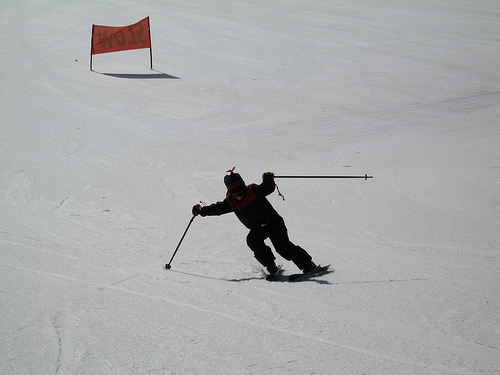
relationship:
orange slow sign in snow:
[90, 14, 155, 76] [4, 4, 496, 372]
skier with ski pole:
[194, 168, 325, 283] [164, 215, 196, 273]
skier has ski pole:
[194, 168, 325, 283] [269, 173, 376, 182]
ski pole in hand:
[164, 215, 196, 273] [190, 202, 203, 218]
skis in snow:
[245, 266, 334, 290] [4, 4, 496, 372]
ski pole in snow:
[164, 215, 196, 273] [4, 4, 496, 372]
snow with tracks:
[4, 4, 496, 372] [43, 267, 162, 370]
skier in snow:
[194, 168, 325, 283] [4, 4, 496, 372]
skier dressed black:
[194, 168, 325, 283] [202, 187, 310, 270]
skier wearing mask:
[194, 168, 325, 283] [232, 192, 247, 203]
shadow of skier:
[227, 276, 338, 290] [194, 168, 325, 283]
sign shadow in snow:
[98, 70, 184, 81] [4, 4, 496, 372]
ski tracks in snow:
[261, 86, 486, 169] [4, 4, 496, 372]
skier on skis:
[194, 168, 325, 283] [245, 266, 334, 290]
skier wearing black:
[194, 168, 325, 283] [202, 187, 310, 270]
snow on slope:
[4, 4, 496, 372] [2, 2, 490, 166]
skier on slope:
[194, 168, 325, 283] [2, 2, 490, 166]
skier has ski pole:
[194, 168, 325, 283] [164, 215, 196, 273]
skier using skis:
[194, 168, 325, 283] [245, 266, 334, 290]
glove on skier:
[259, 168, 279, 186] [194, 168, 325, 283]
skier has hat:
[194, 168, 325, 283] [224, 167, 247, 195]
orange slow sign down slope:
[90, 14, 155, 76] [2, 2, 490, 166]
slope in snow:
[2, 2, 490, 166] [4, 4, 496, 372]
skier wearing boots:
[194, 168, 325, 283] [262, 257, 318, 272]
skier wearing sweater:
[194, 168, 325, 283] [201, 179, 283, 224]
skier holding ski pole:
[194, 168, 325, 283] [269, 173, 376, 182]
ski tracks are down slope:
[261, 86, 486, 169] [2, 2, 490, 166]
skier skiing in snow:
[194, 168, 325, 283] [4, 4, 496, 372]